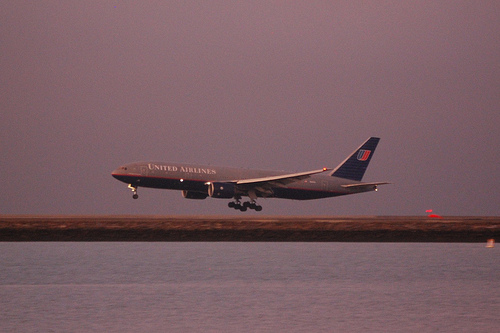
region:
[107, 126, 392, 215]
airplane with landing gear down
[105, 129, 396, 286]
airplane over land and water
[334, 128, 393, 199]
tail wings of an aircraft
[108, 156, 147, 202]
nose cone of an airplane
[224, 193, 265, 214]
landing gear of an airplane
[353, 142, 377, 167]
logo for United Airlines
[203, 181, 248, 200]
jet engine of an aircraft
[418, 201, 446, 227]
orange windsock on airstrip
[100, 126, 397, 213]
aircraft in the sky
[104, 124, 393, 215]
aircraft with jet engines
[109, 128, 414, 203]
this is a plane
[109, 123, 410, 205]
the plane is departing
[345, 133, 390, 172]
this is the tail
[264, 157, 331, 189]
this is the wing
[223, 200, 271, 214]
these are the wheels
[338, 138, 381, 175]
the tail is blue in color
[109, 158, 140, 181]
the head is streamlined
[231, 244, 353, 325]
water is beside the plane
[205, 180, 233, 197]
this is the propeller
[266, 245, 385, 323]
the water is calm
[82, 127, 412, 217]
Airplane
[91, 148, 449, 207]
Flown by United Airlines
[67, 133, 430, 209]
The airplane is in the air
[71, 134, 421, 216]
The airplane is above a body of water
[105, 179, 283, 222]
The plane's wheels are out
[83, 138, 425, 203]
Left side of the plane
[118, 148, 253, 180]
Font is white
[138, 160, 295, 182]
Windows along the side of the plane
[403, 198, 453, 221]
Red flag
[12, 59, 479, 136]
No clouds in the sky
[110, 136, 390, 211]
commercial jetliner coming in for a landing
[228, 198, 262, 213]
rear landing gear is deployed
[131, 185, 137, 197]
front landing gear is deployed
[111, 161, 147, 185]
nose is tilted slightly up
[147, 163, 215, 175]
company that owns the plane printed in white text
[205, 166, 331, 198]
port side wing and engine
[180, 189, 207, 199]
starboard engine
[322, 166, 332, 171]
red light on the wingtip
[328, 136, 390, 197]
tail section is grey and blue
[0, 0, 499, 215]
sky is dark and grey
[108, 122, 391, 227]
A plane about to take off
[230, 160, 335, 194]
Wing of a plane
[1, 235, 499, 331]
Blue and very calm water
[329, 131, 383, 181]
Tail of the plane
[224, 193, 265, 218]
Round wheels under plane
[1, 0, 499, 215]
The sky appears overcast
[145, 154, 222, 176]
The words "UNITED AIRLINES" on side of the plane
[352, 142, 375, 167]
A blue and red symbol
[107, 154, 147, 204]
The front of the plane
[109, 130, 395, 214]
A gray and blue airplane